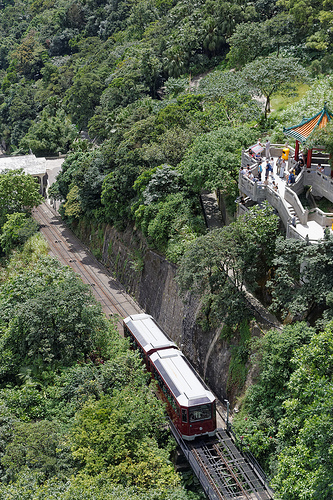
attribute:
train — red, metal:
[121, 316, 218, 444]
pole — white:
[222, 399, 234, 437]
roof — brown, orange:
[285, 102, 331, 140]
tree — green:
[240, 55, 309, 116]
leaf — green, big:
[294, 91, 302, 97]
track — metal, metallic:
[34, 201, 148, 317]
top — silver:
[154, 350, 220, 412]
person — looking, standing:
[255, 162, 264, 181]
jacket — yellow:
[281, 147, 291, 161]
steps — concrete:
[281, 195, 307, 226]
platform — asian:
[237, 141, 303, 203]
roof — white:
[123, 311, 179, 350]